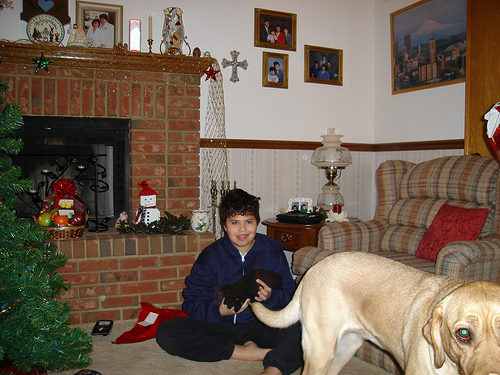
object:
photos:
[301, 44, 344, 89]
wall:
[0, 0, 375, 243]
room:
[0, 0, 499, 373]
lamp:
[309, 126, 354, 217]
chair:
[290, 154, 498, 374]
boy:
[156, 186, 307, 374]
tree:
[0, 85, 94, 367]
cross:
[215, 48, 248, 85]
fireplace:
[0, 42, 216, 327]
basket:
[47, 224, 84, 240]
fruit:
[54, 217, 69, 228]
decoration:
[133, 178, 162, 225]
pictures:
[251, 7, 297, 53]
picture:
[71, 0, 124, 48]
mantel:
[0, 43, 217, 72]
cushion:
[414, 203, 488, 262]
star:
[35, 52, 53, 75]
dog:
[250, 250, 498, 374]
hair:
[214, 187, 261, 225]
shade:
[310, 135, 353, 166]